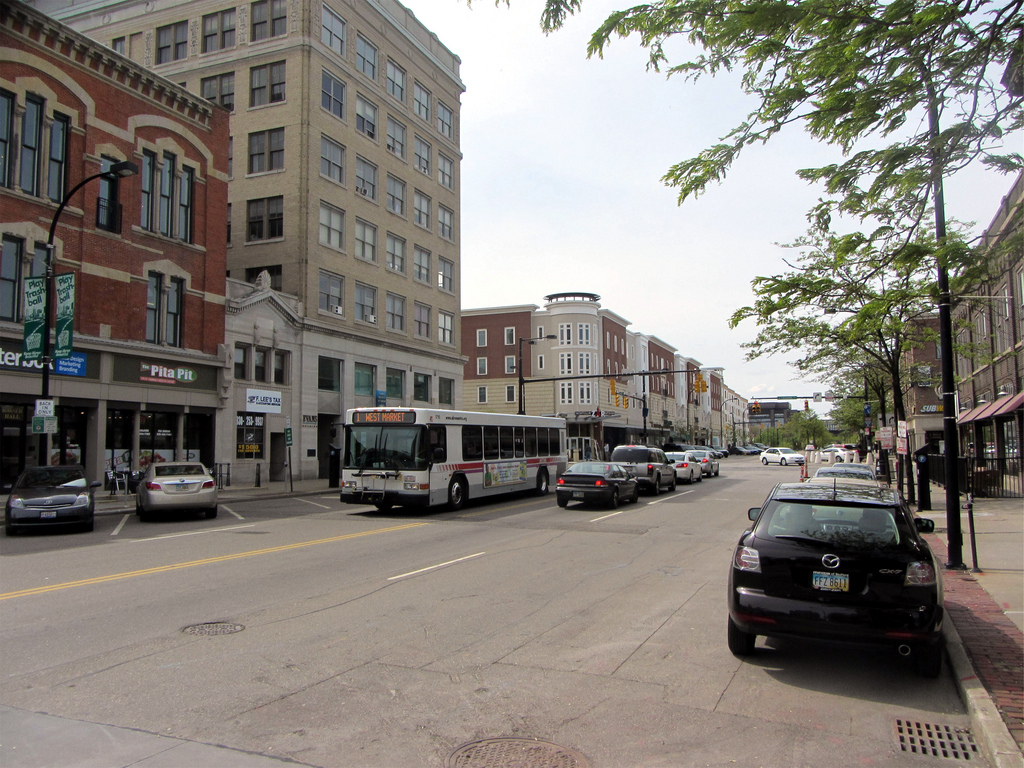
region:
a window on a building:
[246, 6, 276, 45]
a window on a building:
[235, 136, 267, 171]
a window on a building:
[255, 198, 287, 227]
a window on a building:
[308, 154, 341, 181]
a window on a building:
[401, 228, 430, 299]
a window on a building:
[435, 244, 462, 293]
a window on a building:
[319, 279, 342, 317]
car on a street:
[722, 450, 956, 663]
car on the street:
[541, 446, 641, 519]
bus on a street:
[315, 397, 467, 537]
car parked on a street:
[118, 441, 224, 515]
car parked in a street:
[7, 459, 97, 546]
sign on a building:
[124, 345, 202, 404]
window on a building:
[294, 336, 345, 398]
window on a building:
[299, 125, 350, 190]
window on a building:
[450, 316, 498, 355]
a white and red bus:
[316, 376, 576, 535]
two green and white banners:
[19, 256, 99, 380]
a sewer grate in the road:
[893, 701, 958, 765]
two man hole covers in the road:
[179, 603, 604, 766]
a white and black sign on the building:
[245, 382, 300, 418]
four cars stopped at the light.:
[527, 449, 724, 508]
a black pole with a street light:
[13, 114, 153, 513]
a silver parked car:
[126, 446, 257, 541]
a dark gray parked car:
[9, 451, 99, 528]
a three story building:
[2, 5, 224, 492]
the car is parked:
[10, 467, 93, 526]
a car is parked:
[138, 463, 218, 515]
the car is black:
[724, 489, 940, 668]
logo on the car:
[819, 554, 843, 568]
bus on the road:
[346, 410, 562, 509]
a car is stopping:
[555, 461, 633, 503]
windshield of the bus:
[342, 422, 420, 473]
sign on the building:
[245, 391, 284, 414]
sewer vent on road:
[895, 714, 982, 760]